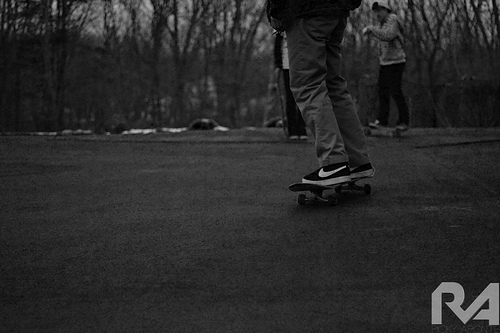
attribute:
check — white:
[318, 161, 345, 176]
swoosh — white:
[312, 158, 352, 178]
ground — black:
[18, 166, 246, 323]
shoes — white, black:
[298, 161, 396, 189]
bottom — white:
[299, 177, 355, 189]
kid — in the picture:
[356, 7, 446, 150]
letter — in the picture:
[461, 278, 491, 331]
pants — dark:
[381, 65, 409, 121]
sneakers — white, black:
[282, 129, 387, 190]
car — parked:
[188, 114, 222, 134]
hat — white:
[362, 3, 398, 18]